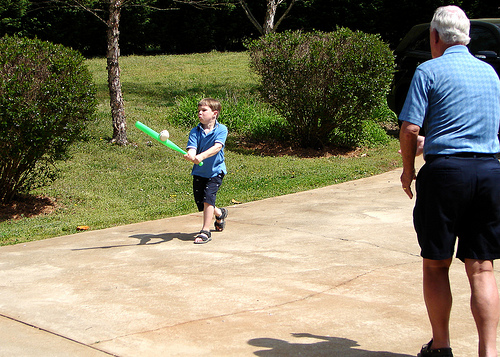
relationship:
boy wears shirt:
[186, 98, 228, 244] [187, 130, 244, 185]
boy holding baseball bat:
[182, 92, 232, 247] [134, 120, 204, 166]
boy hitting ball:
[186, 98, 228, 244] [159, 128, 169, 141]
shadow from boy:
[128, 231, 201, 246] [182, 92, 232, 247]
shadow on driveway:
[128, 231, 201, 246] [19, 150, 403, 357]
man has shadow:
[398, 7, 500, 357] [259, 335, 298, 355]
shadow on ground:
[259, 335, 298, 355] [1, 49, 499, 354]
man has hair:
[398, 7, 500, 357] [428, 5, 472, 49]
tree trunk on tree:
[106, 1, 126, 149] [62, 0, 174, 147]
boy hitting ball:
[182, 92, 232, 247] [156, 125, 173, 142]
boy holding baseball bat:
[182, 92, 232, 247] [134, 117, 204, 170]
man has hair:
[398, 7, 500, 357] [433, 5, 472, 43]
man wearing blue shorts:
[398, 7, 500, 357] [412, 147, 499, 273]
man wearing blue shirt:
[398, 7, 500, 357] [408, 53, 499, 168]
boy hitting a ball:
[182, 92, 232, 247] [155, 127, 172, 140]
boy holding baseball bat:
[186, 98, 228, 244] [134, 120, 204, 166]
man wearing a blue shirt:
[398, 7, 500, 357] [399, 44, 500, 155]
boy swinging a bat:
[186, 98, 228, 244] [130, 120, 199, 160]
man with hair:
[398, 7, 500, 357] [433, 5, 472, 43]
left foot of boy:
[192, 227, 212, 245] [174, 90, 234, 245]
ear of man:
[429, 19, 446, 49] [398, 7, 500, 357]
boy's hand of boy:
[183, 151, 196, 160] [186, 95, 229, 242]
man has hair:
[410, 7, 499, 355] [436, 4, 467, 38]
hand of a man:
[367, 118, 497, 206] [389, 17, 497, 314]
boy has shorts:
[186, 98, 228, 244] [189, 168, 225, 211]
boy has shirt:
[186, 98, 228, 244] [183, 125, 231, 180]